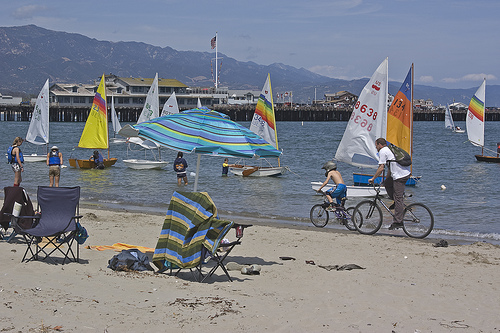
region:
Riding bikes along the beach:
[274, 137, 464, 254]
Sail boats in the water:
[312, 45, 467, 225]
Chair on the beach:
[133, 135, 255, 310]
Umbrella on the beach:
[112, 80, 312, 185]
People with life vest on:
[15, 117, 93, 221]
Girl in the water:
[166, 141, 206, 188]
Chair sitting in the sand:
[24, 159, 149, 331]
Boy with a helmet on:
[298, 154, 376, 234]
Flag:
[191, 30, 250, 92]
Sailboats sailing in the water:
[201, 42, 471, 230]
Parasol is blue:
[122, 97, 288, 207]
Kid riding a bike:
[308, 154, 368, 239]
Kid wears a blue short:
[304, 147, 367, 238]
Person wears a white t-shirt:
[354, 129, 444, 248]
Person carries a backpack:
[344, 129, 442, 254]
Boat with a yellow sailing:
[59, 57, 127, 176]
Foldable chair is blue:
[8, 176, 94, 277]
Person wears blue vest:
[39, 142, 73, 192]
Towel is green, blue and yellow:
[137, 182, 228, 304]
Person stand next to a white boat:
[216, 71, 290, 191]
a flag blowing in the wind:
[207, 30, 219, 50]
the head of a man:
[374, 137, 387, 151]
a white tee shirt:
[376, 145, 412, 181]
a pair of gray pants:
[381, 175, 411, 222]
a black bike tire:
[349, 198, 384, 235]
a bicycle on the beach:
[350, 177, 437, 239]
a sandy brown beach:
[0, 195, 499, 331]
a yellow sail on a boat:
[77, 71, 108, 151]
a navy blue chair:
[7, 183, 87, 264]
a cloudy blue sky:
[0, 0, 499, 90]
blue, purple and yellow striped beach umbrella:
[128, 100, 307, 192]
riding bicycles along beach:
[246, 128, 433, 259]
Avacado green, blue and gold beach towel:
[120, 178, 235, 303]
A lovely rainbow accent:
[243, 86, 282, 132]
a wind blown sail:
[463, 45, 489, 177]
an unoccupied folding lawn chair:
[26, 173, 97, 282]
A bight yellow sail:
[65, 77, 125, 155]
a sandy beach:
[279, 178, 498, 316]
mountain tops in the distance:
[8, 8, 353, 88]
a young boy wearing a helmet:
[313, 133, 342, 189]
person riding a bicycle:
[349, 133, 444, 248]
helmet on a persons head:
[317, 157, 339, 178]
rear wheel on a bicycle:
[395, 198, 439, 244]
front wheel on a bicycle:
[349, 196, 386, 238]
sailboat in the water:
[62, 65, 121, 175]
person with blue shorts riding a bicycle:
[310, 155, 352, 225]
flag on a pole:
[204, 27, 226, 70]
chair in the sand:
[5, 177, 92, 271]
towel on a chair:
[147, 185, 241, 276]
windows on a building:
[54, 92, 89, 106]